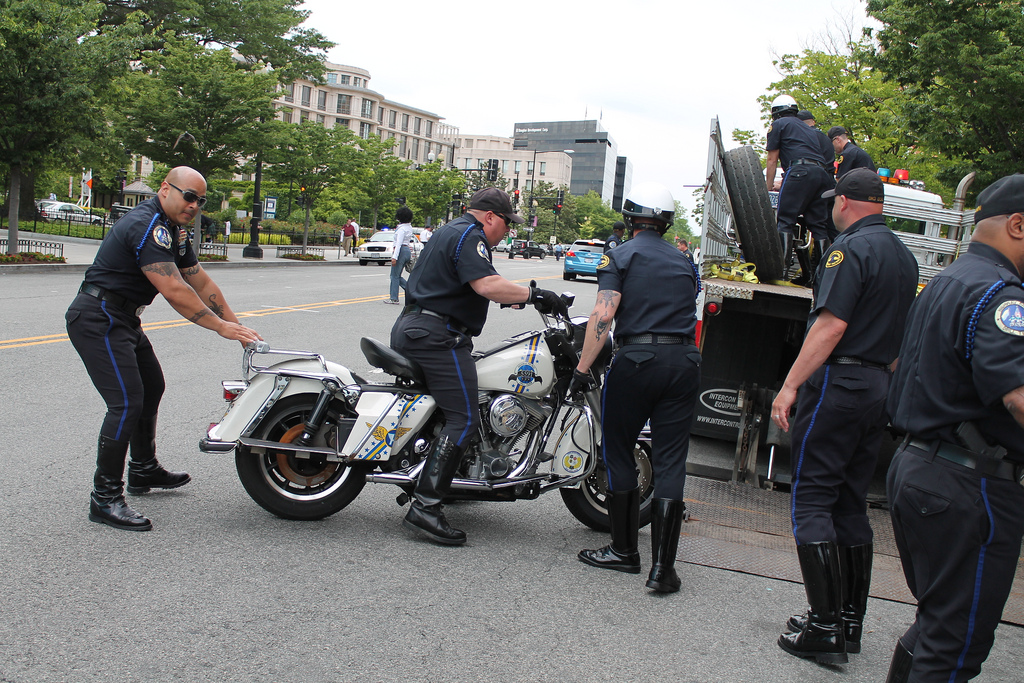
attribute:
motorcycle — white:
[197, 273, 681, 526]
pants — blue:
[772, 163, 829, 269]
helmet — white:
[619, 178, 682, 218]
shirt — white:
[390, 217, 419, 257]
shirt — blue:
[899, 238, 993, 457]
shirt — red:
[336, 217, 360, 237]